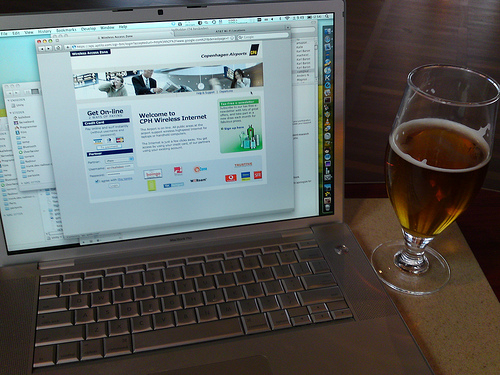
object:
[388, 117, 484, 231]
beer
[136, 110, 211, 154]
news article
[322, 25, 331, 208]
task bar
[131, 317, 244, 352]
bar key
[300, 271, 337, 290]
enter key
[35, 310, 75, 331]
lock key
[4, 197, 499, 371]
desk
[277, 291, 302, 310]
key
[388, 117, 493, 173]
foam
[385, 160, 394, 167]
marking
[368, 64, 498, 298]
goblet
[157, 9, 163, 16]
camera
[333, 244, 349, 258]
button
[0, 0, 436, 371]
laptop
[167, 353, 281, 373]
pad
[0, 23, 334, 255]
window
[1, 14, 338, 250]
monitor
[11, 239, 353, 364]
keyboard